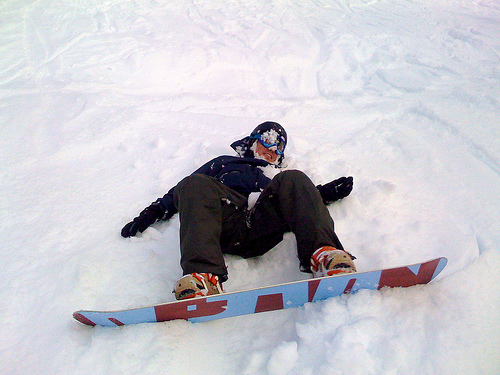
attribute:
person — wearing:
[115, 89, 398, 351]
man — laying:
[119, 114, 359, 299]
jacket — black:
[158, 157, 286, 219]